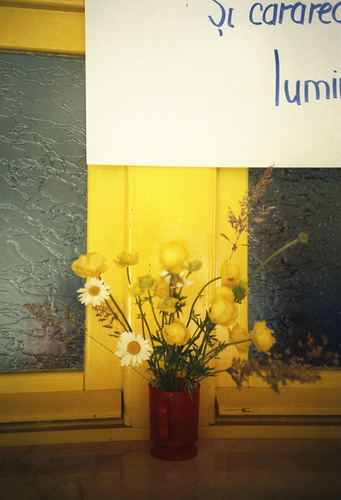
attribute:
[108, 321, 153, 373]
flower — white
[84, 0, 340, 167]
paper — white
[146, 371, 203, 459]
mug — plastic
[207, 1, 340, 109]
writing — blue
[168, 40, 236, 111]
photo — brown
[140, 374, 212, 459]
mug — maroon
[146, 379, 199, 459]
jug — red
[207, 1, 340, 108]
words — blue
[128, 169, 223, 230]
wall — yellow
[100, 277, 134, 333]
stalk — green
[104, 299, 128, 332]
stalk — green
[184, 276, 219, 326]
stalk — green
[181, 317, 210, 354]
stalk — green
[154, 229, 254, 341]
flowers — yellow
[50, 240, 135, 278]
flowers — yellow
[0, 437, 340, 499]
floor — smooth